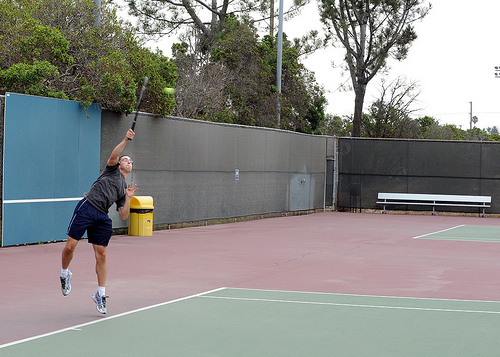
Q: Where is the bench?
A: Against the gate.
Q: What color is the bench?
A: White.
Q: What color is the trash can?
A: Yellow.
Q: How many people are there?
A: One.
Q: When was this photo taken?
A: Daytime.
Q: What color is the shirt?
A: Grey.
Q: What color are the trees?
A: Green.